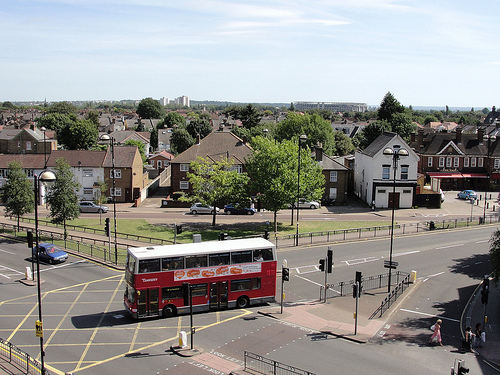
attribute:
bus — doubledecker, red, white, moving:
[121, 234, 280, 321]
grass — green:
[9, 217, 398, 246]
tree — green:
[178, 155, 252, 226]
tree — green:
[242, 135, 326, 236]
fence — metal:
[317, 269, 411, 324]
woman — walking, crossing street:
[425, 317, 447, 349]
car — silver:
[76, 199, 112, 215]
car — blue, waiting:
[30, 240, 70, 266]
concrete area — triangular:
[256, 262, 423, 345]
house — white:
[353, 130, 420, 210]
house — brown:
[302, 146, 351, 207]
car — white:
[190, 200, 221, 216]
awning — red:
[426, 170, 490, 181]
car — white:
[284, 195, 322, 213]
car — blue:
[224, 204, 257, 219]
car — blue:
[455, 188, 478, 203]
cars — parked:
[189, 199, 255, 217]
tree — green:
[45, 158, 80, 242]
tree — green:
[1, 162, 32, 234]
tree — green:
[54, 117, 99, 152]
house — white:
[1, 153, 48, 203]